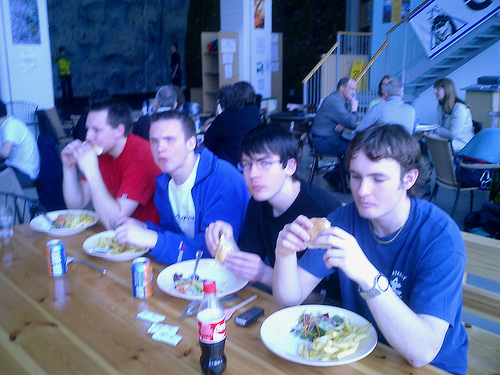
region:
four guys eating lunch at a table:
[60, 105, 469, 374]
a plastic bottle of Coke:
[197, 280, 228, 372]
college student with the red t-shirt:
[63, 104, 159, 225]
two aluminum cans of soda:
[45, 240, 153, 298]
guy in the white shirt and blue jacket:
[112, 110, 249, 260]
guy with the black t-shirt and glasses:
[202, 125, 338, 286]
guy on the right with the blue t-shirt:
[281, 123, 466, 372]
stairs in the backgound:
[307, 0, 497, 120]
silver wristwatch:
[359, 276, 388, 301]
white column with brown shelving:
[200, 5, 285, 99]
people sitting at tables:
[0, 77, 496, 372]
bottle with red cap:
[199, 279, 224, 373]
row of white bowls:
[37, 208, 378, 365]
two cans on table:
[45, 238, 153, 300]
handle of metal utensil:
[193, 248, 205, 279]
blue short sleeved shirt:
[300, 195, 468, 374]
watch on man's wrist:
[358, 273, 388, 299]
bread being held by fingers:
[293, 215, 340, 262]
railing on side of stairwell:
[304, 5, 494, 124]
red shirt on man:
[84, 134, 160, 221]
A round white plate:
[259, 300, 384, 368]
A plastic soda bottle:
[194, 278, 234, 372]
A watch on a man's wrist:
[359, 272, 392, 305]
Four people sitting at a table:
[304, 75, 477, 184]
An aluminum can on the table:
[129, 257, 154, 302]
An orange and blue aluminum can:
[42, 237, 69, 279]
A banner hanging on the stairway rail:
[404, 1, 498, 61]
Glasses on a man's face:
[232, 157, 292, 171]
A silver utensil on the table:
[65, 251, 111, 278]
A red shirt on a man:
[69, 133, 163, 228]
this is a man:
[313, 118, 453, 352]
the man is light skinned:
[398, 300, 420, 347]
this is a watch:
[372, 255, 389, 294]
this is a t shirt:
[398, 223, 446, 298]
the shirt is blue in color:
[420, 229, 452, 290]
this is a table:
[49, 308, 113, 373]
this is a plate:
[262, 313, 288, 363]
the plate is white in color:
[263, 312, 285, 356]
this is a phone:
[233, 306, 259, 318]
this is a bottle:
[202, 279, 245, 373]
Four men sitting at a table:
[26, 102, 468, 373]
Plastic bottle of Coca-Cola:
[193, 274, 230, 372]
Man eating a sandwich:
[275, 121, 470, 358]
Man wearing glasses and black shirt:
[235, 126, 337, 271]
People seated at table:
[310, 71, 470, 142]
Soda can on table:
[127, 255, 152, 302]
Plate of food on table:
[257, 300, 377, 365]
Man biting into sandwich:
[60, 93, 148, 223]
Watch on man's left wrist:
[358, 270, 391, 300]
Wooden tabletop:
[0, 226, 449, 371]